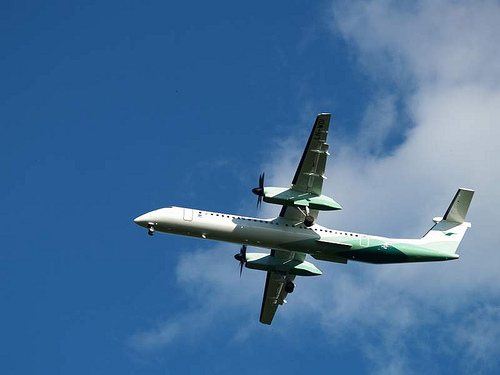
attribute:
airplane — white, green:
[132, 113, 477, 326]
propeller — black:
[252, 172, 267, 207]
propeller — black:
[234, 244, 250, 278]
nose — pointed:
[132, 208, 164, 235]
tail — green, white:
[417, 186, 476, 254]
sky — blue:
[2, 3, 499, 372]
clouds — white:
[123, 1, 500, 372]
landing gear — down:
[147, 207, 315, 291]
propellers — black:
[234, 172, 265, 275]